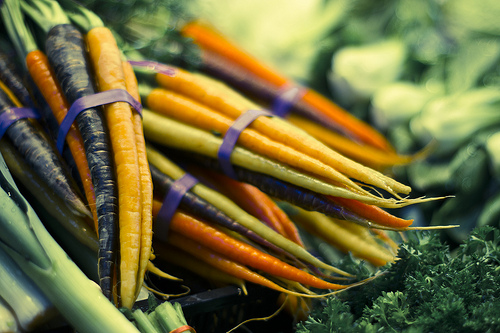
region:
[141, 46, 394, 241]
the peppers in a bundle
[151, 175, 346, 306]
the peppers in a bundle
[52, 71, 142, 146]
the blue band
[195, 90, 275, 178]
the blue band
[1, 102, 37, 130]
the blue band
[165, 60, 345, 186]
the pepper is orange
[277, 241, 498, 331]
the basil leaves beside the stacks of peppers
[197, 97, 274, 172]
purple band holding vegetable together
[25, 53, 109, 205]
orange vegetable in bundle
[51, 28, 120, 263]
purple vegetable in bundle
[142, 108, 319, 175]
yellow vegetable in bundle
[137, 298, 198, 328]
green vegetables in bundle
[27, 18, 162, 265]
bundle of different vegetables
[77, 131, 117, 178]
dents on purple vegetable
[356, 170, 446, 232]
frayed end of vegetable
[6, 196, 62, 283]
green vegetable with one side split open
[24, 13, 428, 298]
fresh carrots wrapped in a bundle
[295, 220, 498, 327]
leaves of the carrots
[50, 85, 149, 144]
purple band around the carrots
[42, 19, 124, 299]
this carrot is purple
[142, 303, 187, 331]
wrapped bunch of green vegetables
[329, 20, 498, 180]
blurry area of green vegetables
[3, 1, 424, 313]
colorful carrots wrapped in a bunch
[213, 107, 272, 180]
purple rubber band around the carrots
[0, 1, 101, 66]
leaves of the carrots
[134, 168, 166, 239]
Orange carrot in blue band.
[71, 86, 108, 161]
Dark colored carrot in blue band.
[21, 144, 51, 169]
Dark colored carrot in blue band.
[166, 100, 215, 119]
Orange carrot in blue band.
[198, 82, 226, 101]
Orange carrot in blue band.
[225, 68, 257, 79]
Dark colored carrot in blue band.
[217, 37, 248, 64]
Orange carrot in blue band.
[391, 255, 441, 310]
Green parsley near carrots.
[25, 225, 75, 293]
Green vegetable stalk near carrots.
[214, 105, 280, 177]
A purple rubber band holding carrots.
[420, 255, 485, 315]
A bunch of fresh parsely.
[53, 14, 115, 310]
Only one purple carrot in a bunch of others.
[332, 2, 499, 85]
Out of focus bok choy in the background.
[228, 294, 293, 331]
A root extending from a carrot.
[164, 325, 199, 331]
A red rubber band holding carrots.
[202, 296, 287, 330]
A dark black hole under colorful carrots.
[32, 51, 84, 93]
A room's light bouncing off colorful carrots.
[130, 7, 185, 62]
Out of focus carrot tops.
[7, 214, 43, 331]
Pieces of green onions.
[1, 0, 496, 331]
Array of fresh vegetables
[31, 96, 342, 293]
Array of fresh vegetables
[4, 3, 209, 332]
Array of fresh vegetables